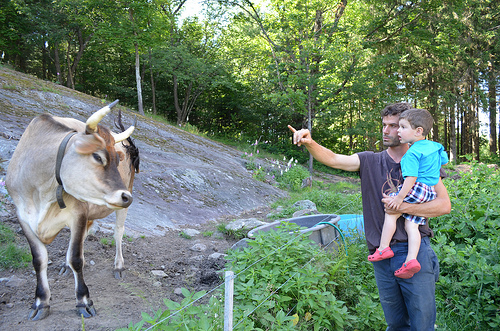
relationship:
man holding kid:
[334, 114, 400, 331] [400, 111, 440, 270]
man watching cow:
[334, 114, 400, 331] [6, 87, 157, 313]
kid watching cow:
[400, 111, 440, 270] [6, 87, 157, 313]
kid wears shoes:
[400, 111, 440, 270] [370, 240, 445, 285]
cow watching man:
[6, 87, 157, 313] [334, 114, 400, 331]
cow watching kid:
[6, 87, 157, 313] [400, 111, 440, 270]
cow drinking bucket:
[6, 87, 157, 313] [223, 212, 350, 262]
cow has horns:
[6, 87, 157, 313] [74, 103, 145, 138]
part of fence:
[225, 275, 259, 295] [169, 262, 295, 308]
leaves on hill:
[0, 0, 500, 156] [166, 117, 230, 192]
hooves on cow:
[33, 279, 109, 315] [6, 87, 157, 313]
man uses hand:
[334, 114, 400, 331] [280, 128, 336, 149]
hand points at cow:
[280, 128, 336, 149] [6, 87, 157, 313]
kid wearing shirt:
[400, 111, 440, 270] [398, 148, 444, 182]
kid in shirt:
[400, 111, 440, 270] [398, 148, 444, 182]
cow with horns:
[6, 87, 157, 313] [74, 103, 145, 138]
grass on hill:
[290, 174, 326, 194] [166, 117, 230, 192]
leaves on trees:
[396, 26, 409, 36] [95, 30, 242, 111]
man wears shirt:
[334, 114, 400, 331] [378, 153, 387, 160]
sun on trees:
[233, 26, 277, 69] [95, 30, 242, 111]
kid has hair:
[400, 111, 440, 270] [410, 119, 444, 132]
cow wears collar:
[6, 87, 157, 313] [54, 130, 70, 193]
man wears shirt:
[334, 114, 400, 331] [398, 148, 444, 182]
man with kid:
[334, 114, 400, 331] [400, 111, 440, 270]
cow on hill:
[6, 87, 157, 313] [166, 117, 230, 192]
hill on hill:
[0, 66, 312, 241] [166, 117, 230, 192]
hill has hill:
[166, 117, 230, 192] [0, 66, 312, 241]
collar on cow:
[54, 130, 70, 193] [6, 87, 157, 313]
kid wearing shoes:
[400, 111, 440, 270] [370, 240, 445, 285]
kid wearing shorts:
[400, 111, 440, 270] [412, 178, 435, 203]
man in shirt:
[334, 114, 400, 331] [398, 148, 444, 182]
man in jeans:
[334, 114, 400, 331] [394, 281, 435, 316]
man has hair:
[334, 114, 400, 331] [410, 119, 444, 132]